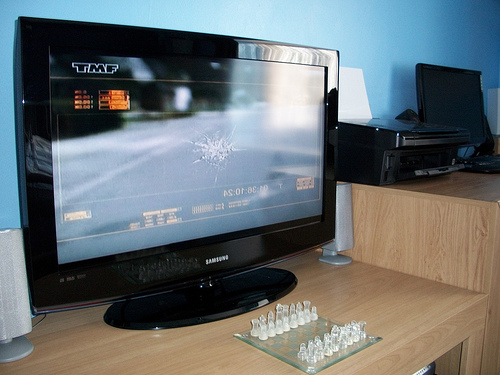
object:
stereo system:
[315, 114, 477, 197]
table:
[7, 245, 499, 371]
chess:
[234, 299, 382, 373]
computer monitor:
[413, 62, 498, 155]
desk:
[327, 166, 497, 373]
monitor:
[14, 16, 340, 307]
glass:
[232, 317, 381, 374]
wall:
[0, 0, 497, 255]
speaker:
[316, 181, 356, 268]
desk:
[0, 240, 500, 375]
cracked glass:
[185, 125, 246, 182]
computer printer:
[336, 119, 465, 181]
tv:
[19, 17, 339, 331]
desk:
[1, 166, 500, 373]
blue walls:
[309, 7, 429, 107]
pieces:
[248, 297, 318, 339]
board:
[231, 315, 382, 373]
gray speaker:
[0, 228, 32, 364]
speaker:
[320, 184, 353, 268]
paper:
[337, 67, 372, 119]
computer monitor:
[50, 53, 329, 265]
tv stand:
[102, 267, 297, 332]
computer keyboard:
[461, 152, 500, 174]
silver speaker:
[1, 224, 38, 370]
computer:
[13, 16, 339, 330]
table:
[0, 287, 483, 374]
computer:
[9, 16, 478, 330]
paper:
[330, 64, 388, 140]